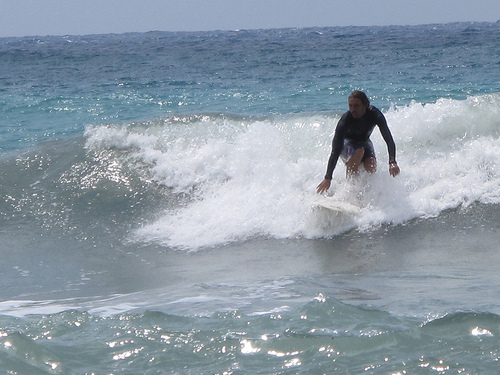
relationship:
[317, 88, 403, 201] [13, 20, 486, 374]
person in water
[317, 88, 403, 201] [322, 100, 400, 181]
person wearing shirt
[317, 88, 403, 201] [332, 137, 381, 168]
person wearing bottoms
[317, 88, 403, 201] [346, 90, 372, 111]
person has hair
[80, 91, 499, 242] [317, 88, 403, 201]
wave rolling by person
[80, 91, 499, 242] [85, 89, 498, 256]
wave has cap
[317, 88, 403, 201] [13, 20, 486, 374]
person close to water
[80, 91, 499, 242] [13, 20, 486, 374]
wave in water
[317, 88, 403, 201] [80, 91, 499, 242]
person surfing on wave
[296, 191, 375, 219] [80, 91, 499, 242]
surfboard in wave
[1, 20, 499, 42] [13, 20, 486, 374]
horizon above water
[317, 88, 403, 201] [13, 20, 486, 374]
person surfing in water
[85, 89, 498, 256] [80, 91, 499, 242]
cap on wave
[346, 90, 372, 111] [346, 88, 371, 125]
hair on head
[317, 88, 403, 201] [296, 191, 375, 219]
person reaching for surfboard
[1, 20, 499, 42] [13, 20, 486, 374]
horizon over water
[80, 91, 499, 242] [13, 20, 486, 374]
wave rippling water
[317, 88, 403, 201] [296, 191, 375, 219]
person standing on surfboard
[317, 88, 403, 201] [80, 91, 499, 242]
person on a wave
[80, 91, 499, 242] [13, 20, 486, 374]
wave crashing into water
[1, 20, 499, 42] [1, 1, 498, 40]
horizon against sky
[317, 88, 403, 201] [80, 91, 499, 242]
person riding wave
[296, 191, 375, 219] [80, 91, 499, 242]
surfboard emerging from wave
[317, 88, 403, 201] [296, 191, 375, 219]
person on surfboard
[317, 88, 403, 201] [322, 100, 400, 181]
person has shirt